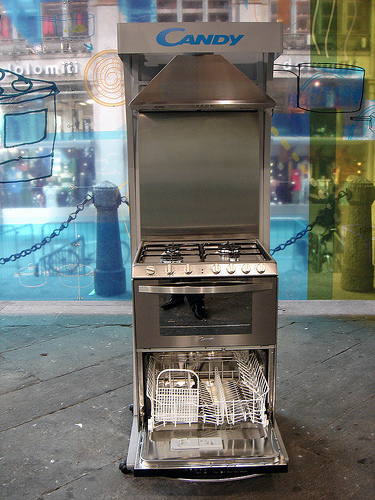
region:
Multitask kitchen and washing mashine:
[119, 51, 288, 474]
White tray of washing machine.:
[136, 353, 269, 423]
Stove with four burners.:
[132, 236, 271, 266]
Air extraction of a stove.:
[122, 49, 277, 112]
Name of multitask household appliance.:
[150, 21, 254, 54]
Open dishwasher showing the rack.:
[115, 345, 301, 474]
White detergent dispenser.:
[167, 432, 228, 450]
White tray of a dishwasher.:
[146, 352, 269, 424]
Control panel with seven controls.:
[142, 261, 271, 274]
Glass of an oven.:
[156, 279, 254, 337]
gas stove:
[131, 238, 278, 279]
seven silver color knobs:
[145, 263, 268, 274]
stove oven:
[131, 276, 281, 346]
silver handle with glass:
[138, 279, 275, 338]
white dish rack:
[141, 349, 270, 429]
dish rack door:
[133, 349, 291, 473]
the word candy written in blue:
[156, 25, 244, 47]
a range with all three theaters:
[116, 21, 296, 483]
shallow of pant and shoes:
[159, 292, 209, 318]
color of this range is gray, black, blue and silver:
[116, 21, 290, 478]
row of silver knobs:
[140, 262, 271, 275]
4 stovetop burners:
[133, 239, 271, 265]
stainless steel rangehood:
[122, 54, 278, 113]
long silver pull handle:
[135, 282, 274, 295]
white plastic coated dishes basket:
[146, 351, 270, 428]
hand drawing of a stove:
[0, 52, 67, 192]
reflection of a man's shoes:
[158, 293, 218, 326]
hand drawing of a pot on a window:
[273, 58, 366, 115]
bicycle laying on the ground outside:
[44, 234, 129, 274]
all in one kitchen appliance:
[114, 20, 291, 482]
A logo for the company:
[155, 20, 245, 51]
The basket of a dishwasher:
[144, 350, 270, 425]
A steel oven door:
[131, 277, 278, 347]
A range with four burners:
[133, 237, 273, 261]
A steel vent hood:
[129, 51, 275, 110]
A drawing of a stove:
[0, 66, 58, 181]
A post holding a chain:
[90, 180, 128, 295]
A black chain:
[0, 193, 93, 264]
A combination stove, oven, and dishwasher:
[115, 22, 290, 479]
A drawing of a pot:
[272, 64, 363, 113]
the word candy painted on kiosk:
[117, 21, 284, 54]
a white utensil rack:
[147, 354, 270, 426]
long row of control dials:
[132, 264, 276, 275]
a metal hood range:
[128, 56, 275, 107]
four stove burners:
[139, 243, 271, 263]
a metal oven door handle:
[139, 285, 271, 293]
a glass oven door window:
[159, 292, 254, 335]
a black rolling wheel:
[119, 461, 130, 476]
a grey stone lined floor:
[2, 327, 120, 492]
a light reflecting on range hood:
[211, 98, 240, 109]